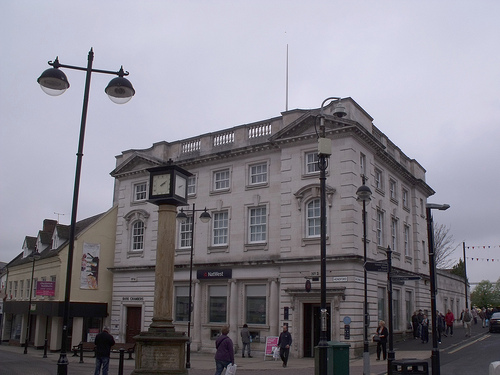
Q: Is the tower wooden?
A: Yes, the tower is wooden.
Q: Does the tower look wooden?
A: Yes, the tower is wooden.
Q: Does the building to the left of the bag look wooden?
A: Yes, the tower is wooden.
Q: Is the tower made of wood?
A: Yes, the tower is made of wood.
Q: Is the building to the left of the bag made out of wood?
A: Yes, the tower is made of wood.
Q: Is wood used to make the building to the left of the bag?
A: Yes, the tower is made of wood.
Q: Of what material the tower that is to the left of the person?
A: The tower is made of wood.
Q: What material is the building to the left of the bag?
A: The tower is made of wood.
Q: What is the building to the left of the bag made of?
A: The tower is made of wood.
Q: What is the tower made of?
A: The tower is made of wood.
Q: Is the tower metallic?
A: No, the tower is wooden.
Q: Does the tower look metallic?
A: No, the tower is wooden.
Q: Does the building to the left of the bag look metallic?
A: No, the tower is wooden.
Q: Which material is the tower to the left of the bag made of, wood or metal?
A: The tower is made of wood.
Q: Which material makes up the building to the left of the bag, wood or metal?
A: The tower is made of wood.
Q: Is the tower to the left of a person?
A: Yes, the tower is to the left of a person.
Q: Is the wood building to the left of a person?
A: Yes, the tower is to the left of a person.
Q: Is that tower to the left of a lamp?
A: No, the tower is to the left of a person.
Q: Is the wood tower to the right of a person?
A: No, the tower is to the left of a person.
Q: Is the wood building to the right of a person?
A: No, the tower is to the left of a person.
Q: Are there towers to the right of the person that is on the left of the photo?
A: Yes, there is a tower to the right of the person.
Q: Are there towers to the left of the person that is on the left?
A: No, the tower is to the right of the person.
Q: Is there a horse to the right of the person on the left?
A: No, there is a tower to the right of the person.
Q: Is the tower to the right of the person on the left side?
A: Yes, the tower is to the right of the person.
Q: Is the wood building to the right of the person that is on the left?
A: Yes, the tower is to the right of the person.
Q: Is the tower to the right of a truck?
A: No, the tower is to the right of the person.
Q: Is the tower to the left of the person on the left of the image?
A: No, the tower is to the right of the person.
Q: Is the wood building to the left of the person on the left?
A: No, the tower is to the right of the person.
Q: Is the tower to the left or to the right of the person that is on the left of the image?
A: The tower is to the right of the person.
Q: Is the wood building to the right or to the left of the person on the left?
A: The tower is to the right of the person.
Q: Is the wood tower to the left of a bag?
A: Yes, the tower is to the left of a bag.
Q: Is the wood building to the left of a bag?
A: Yes, the tower is to the left of a bag.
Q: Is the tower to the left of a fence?
A: No, the tower is to the left of a bag.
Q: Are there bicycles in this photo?
A: No, there are no bicycles.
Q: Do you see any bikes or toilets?
A: No, there are no bikes or toilets.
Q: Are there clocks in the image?
A: Yes, there is a clock.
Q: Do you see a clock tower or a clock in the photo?
A: Yes, there is a clock.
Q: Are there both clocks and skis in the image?
A: No, there is a clock but no skis.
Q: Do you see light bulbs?
A: No, there are no light bulbs.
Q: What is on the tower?
A: The clock is on the tower.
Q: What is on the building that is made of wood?
A: The clock is on the tower.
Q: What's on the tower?
A: The clock is on the tower.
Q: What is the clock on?
A: The clock is on the tower.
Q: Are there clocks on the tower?
A: Yes, there is a clock on the tower.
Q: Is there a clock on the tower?
A: Yes, there is a clock on the tower.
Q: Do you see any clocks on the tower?
A: Yes, there is a clock on the tower.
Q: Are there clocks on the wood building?
A: Yes, there is a clock on the tower.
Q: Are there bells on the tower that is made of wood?
A: No, there is a clock on the tower.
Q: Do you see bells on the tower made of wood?
A: No, there is a clock on the tower.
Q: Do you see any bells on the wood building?
A: No, there is a clock on the tower.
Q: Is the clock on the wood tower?
A: Yes, the clock is on the tower.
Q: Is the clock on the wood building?
A: Yes, the clock is on the tower.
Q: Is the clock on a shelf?
A: No, the clock is on the tower.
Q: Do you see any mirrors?
A: No, there are no mirrors.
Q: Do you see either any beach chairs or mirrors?
A: No, there are no mirrors or beach chairs.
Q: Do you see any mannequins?
A: No, there are no mannequins.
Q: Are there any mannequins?
A: No, there are no mannequins.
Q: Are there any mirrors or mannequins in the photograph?
A: No, there are no mannequins or mirrors.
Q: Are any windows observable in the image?
A: Yes, there is a window.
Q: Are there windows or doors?
A: Yes, there is a window.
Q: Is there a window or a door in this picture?
A: Yes, there is a window.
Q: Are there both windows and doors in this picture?
A: Yes, there are both a window and doors.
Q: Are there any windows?
A: Yes, there is a window.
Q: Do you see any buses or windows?
A: Yes, there is a window.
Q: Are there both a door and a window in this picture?
A: Yes, there are both a window and a door.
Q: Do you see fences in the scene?
A: No, there are no fences.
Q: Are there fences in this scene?
A: No, there are no fences.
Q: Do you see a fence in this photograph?
A: No, there are no fences.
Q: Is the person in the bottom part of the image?
A: Yes, the person is in the bottom of the image.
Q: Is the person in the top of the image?
A: No, the person is in the bottom of the image.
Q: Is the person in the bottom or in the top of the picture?
A: The person is in the bottom of the image.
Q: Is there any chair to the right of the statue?
A: No, there is a person to the right of the statue.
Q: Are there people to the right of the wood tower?
A: Yes, there is a person to the right of the tower.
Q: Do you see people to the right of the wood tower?
A: Yes, there is a person to the right of the tower.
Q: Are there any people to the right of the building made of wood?
A: Yes, there is a person to the right of the tower.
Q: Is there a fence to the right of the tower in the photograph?
A: No, there is a person to the right of the tower.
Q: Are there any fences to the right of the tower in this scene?
A: No, there is a person to the right of the tower.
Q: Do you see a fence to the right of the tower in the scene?
A: No, there is a person to the right of the tower.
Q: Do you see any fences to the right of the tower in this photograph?
A: No, there is a person to the right of the tower.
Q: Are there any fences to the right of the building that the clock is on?
A: No, there is a person to the right of the tower.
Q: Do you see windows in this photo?
A: Yes, there is a window.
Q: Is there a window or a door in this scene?
A: Yes, there is a window.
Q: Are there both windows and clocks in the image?
A: Yes, there are both a window and a clock.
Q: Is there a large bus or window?
A: Yes, there is a large window.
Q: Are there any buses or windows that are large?
A: Yes, the window is large.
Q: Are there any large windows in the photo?
A: Yes, there is a large window.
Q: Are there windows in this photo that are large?
A: Yes, there is a window that is large.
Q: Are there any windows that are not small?
A: Yes, there is a large window.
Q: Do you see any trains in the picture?
A: No, there are no trains.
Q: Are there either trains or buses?
A: No, there are no trains or buses.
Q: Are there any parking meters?
A: No, there are no parking meters.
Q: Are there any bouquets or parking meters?
A: No, there are no parking meters or bouquets.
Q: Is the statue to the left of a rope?
A: No, the statue is to the left of the bag.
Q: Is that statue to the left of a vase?
A: No, the statue is to the left of a person.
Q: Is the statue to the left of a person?
A: Yes, the statue is to the left of a person.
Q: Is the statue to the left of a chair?
A: No, the statue is to the left of a person.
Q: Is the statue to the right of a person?
A: No, the statue is to the left of a person.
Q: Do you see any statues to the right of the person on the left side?
A: Yes, there is a statue to the right of the person.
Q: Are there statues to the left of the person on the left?
A: No, the statue is to the right of the person.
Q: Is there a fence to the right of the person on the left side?
A: No, there is a statue to the right of the person.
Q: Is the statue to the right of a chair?
A: No, the statue is to the right of a person.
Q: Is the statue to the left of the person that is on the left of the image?
A: No, the statue is to the right of the person.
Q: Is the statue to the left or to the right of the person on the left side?
A: The statue is to the right of the person.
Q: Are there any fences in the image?
A: No, there are no fences.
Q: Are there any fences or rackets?
A: No, there are no fences or rackets.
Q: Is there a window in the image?
A: Yes, there is a window.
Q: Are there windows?
A: Yes, there is a window.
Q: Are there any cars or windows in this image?
A: Yes, there is a window.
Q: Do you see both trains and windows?
A: No, there is a window but no trains.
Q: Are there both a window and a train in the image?
A: No, there is a window but no trains.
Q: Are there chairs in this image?
A: No, there are no chairs.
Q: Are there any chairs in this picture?
A: No, there are no chairs.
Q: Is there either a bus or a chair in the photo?
A: No, there are no chairs or buses.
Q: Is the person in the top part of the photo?
A: No, the person is in the bottom of the image.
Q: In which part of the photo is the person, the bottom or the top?
A: The person is in the bottom of the image.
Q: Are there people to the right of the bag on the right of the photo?
A: Yes, there is a person to the right of the bag.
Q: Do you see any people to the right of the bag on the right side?
A: Yes, there is a person to the right of the bag.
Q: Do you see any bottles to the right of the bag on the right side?
A: No, there is a person to the right of the bag.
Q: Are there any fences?
A: No, there are no fences.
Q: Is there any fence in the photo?
A: No, there are no fences.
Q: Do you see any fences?
A: No, there are no fences.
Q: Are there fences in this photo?
A: No, there are no fences.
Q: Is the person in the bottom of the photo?
A: Yes, the person is in the bottom of the image.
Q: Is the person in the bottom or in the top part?
A: The person is in the bottom of the image.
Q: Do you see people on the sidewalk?
A: Yes, there is a person on the sidewalk.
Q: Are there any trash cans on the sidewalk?
A: No, there is a person on the sidewalk.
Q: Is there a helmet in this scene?
A: No, there are no helmets.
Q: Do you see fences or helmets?
A: No, there are no helmets or fences.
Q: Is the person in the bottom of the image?
A: Yes, the person is in the bottom of the image.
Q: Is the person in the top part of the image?
A: No, the person is in the bottom of the image.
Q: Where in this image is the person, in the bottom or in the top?
A: The person is in the bottom of the image.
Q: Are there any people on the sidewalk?
A: Yes, there is a person on the sidewalk.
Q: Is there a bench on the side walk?
A: No, there is a person on the side walk.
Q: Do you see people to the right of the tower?
A: Yes, there is a person to the right of the tower.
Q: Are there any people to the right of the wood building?
A: Yes, there is a person to the right of the tower.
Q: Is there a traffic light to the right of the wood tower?
A: No, there is a person to the right of the tower.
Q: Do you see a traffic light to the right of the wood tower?
A: No, there is a person to the right of the tower.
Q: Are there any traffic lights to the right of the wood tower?
A: No, there is a person to the right of the tower.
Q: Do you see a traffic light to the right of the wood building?
A: No, there is a person to the right of the tower.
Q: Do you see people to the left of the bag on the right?
A: Yes, there is a person to the left of the bag.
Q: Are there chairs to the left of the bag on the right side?
A: No, there is a person to the left of the bag.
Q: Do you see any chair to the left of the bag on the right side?
A: No, there is a person to the left of the bag.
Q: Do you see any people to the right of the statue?
A: Yes, there is a person to the right of the statue.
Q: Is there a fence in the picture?
A: No, there are no fences.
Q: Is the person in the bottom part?
A: Yes, the person is in the bottom of the image.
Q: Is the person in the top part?
A: No, the person is in the bottom of the image.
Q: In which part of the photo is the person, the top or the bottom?
A: The person is in the bottom of the image.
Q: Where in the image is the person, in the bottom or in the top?
A: The person is in the bottom of the image.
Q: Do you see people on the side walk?
A: Yes, there is a person on the side walk.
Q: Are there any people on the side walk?
A: Yes, there is a person on the side walk.